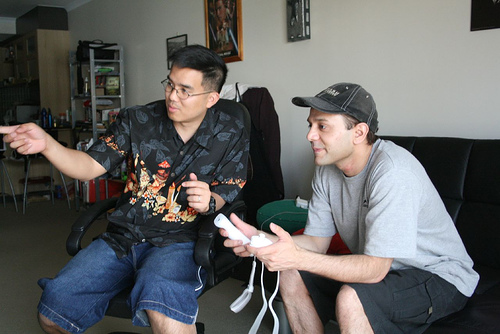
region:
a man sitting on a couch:
[264, 80, 458, 332]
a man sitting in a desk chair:
[42, 64, 235, 296]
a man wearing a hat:
[292, 77, 377, 159]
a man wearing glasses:
[153, 68, 223, 115]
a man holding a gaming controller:
[214, 91, 404, 286]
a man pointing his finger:
[0, 54, 210, 190]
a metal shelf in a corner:
[75, 34, 125, 141]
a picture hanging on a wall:
[201, 4, 252, 66]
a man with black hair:
[161, 43, 230, 100]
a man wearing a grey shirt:
[313, 82, 391, 242]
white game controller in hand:
[212, 211, 269, 263]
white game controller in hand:
[243, 220, 300, 271]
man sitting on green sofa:
[218, 82, 475, 332]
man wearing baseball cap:
[216, 80, 478, 332]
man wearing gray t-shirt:
[214, 84, 482, 331]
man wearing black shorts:
[216, 84, 480, 331]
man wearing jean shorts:
[0, 44, 253, 331]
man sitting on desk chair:
[2, 47, 254, 331]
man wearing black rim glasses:
[2, 46, 254, 332]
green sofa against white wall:
[259, 135, 498, 332]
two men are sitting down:
[84, 50, 479, 242]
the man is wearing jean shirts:
[37, 228, 261, 286]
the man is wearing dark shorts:
[296, 241, 498, 311]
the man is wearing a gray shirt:
[285, 177, 493, 229]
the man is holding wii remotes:
[199, 196, 423, 321]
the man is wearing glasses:
[138, 75, 278, 142]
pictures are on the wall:
[182, 8, 426, 78]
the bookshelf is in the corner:
[54, 33, 175, 280]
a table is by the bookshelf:
[1, 119, 111, 245]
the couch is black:
[420, 125, 494, 242]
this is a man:
[219, 97, 415, 270]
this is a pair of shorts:
[337, 276, 413, 331]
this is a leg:
[324, 296, 379, 321]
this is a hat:
[265, 87, 406, 129]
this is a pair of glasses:
[170, 77, 195, 104]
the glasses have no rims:
[120, 86, 223, 104]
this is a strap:
[215, 259, 244, 327]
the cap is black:
[290, 87, 364, 139]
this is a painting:
[220, 32, 290, 84]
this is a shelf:
[77, 49, 144, 206]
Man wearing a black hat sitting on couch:
[209, 80, 484, 331]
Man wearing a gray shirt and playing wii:
[210, 80, 484, 332]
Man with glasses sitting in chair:
[5, 42, 248, 332]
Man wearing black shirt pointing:
[6, 43, 253, 332]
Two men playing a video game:
[2, 35, 491, 332]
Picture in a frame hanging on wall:
[194, 0, 252, 67]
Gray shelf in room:
[65, 35, 126, 130]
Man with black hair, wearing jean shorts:
[2, 34, 259, 332]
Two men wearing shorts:
[12, 48, 477, 332]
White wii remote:
[203, 203, 293, 283]